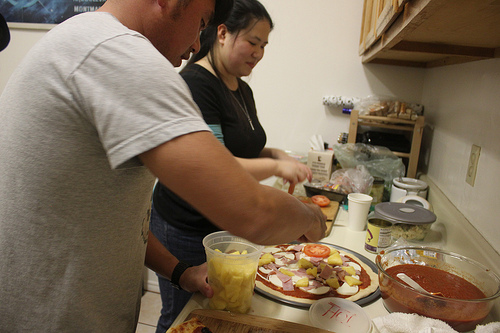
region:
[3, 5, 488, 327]
woman and men in a kitchen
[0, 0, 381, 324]
man making a pizza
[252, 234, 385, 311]
pizza is uncooked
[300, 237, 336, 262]
slice of tomato on pizza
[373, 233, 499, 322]
a bowl of red sauce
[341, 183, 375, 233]
a cup on table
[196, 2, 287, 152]
woman wears black top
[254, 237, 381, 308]
ham over pizza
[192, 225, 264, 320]
cup with cheese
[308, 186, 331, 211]
a slice of tomato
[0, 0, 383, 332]
Man and woman preparing pizza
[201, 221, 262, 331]
Plastic container of pineapple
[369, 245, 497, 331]
Glass bowl of tomato sauce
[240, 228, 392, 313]
Homemade pizza with cheese, meat and veges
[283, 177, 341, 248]
Tomato on wood cutting board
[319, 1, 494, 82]
Upper wooden kitchen cabinets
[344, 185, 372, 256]
White styrofoam cup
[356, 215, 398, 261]
Opened aluminum can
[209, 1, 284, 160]
Silver necklace worn by woman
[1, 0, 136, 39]
Picture hanging on kitchen wall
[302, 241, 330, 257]
piece of food on a pizza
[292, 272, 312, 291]
piece of food on a pizza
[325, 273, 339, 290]
piece of food on a pizza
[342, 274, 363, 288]
piece of food on a pizza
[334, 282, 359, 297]
piece of food on a pizza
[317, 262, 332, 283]
piece of food on a pizza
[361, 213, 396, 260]
metal can with yellow label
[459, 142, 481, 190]
white switch plate on the wall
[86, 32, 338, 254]
arm of a person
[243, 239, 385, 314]
uncooked pizza on a tray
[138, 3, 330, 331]
a man and woman standing at a counter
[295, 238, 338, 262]
a slice of tomatoe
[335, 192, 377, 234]
a white plastic cup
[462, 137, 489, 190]
a electrical outlet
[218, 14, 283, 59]
a woman with black hair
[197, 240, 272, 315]
a container of cut cheese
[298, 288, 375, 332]
a plastic lid to a container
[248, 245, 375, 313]
a round pizza on a pan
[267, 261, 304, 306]
sliced ham on a pizza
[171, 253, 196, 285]
a man wearing a wrist watch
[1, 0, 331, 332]
Man and woman preparing food in the kitchen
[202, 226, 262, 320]
Plastic container with yellow food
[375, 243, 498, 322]
Bowl of red sauce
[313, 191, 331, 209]
Slice of tomato on the cutting board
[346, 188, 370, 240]
WHite cup on the counter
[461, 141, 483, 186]
Electric outlet on the wall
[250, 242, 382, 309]
Uncooked pizza on a tray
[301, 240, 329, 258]
Slice of tomato on the pizza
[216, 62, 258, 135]
Necklace around woman's neck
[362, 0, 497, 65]
Wooden cabinets over counter